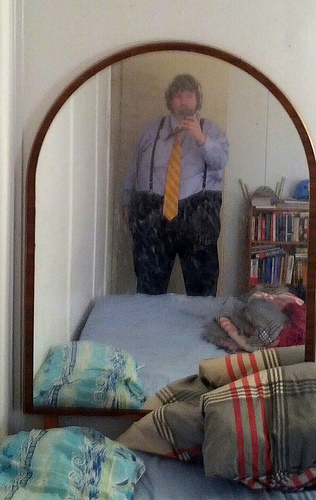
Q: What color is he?
A: White.